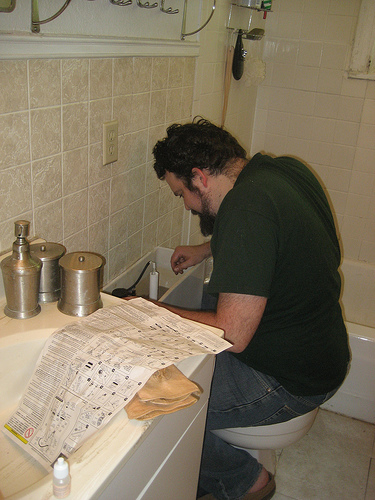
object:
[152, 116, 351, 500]
man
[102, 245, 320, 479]
toilet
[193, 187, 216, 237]
beard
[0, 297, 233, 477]
newspaper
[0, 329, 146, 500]
sink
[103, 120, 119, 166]
outlet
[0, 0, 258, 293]
wall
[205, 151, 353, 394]
shirt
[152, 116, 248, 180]
hair